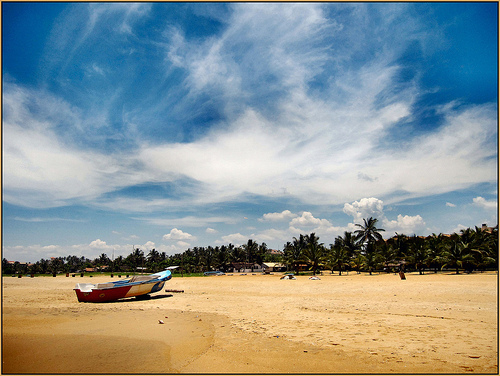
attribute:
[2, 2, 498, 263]
sky — blue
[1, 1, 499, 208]
clouds — wispy, white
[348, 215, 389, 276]
palm tree — green, tall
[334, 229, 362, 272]
palm tree — green, tall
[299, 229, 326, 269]
palm tree — green, tall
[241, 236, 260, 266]
palm tree — green, tall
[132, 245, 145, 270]
palm tree — green, tall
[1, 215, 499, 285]
trees — dense, green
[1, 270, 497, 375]
beach — brown, sandy, golden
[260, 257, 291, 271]
house — tan, brown, white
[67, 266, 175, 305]
boat — propped, tricolored, red, white, blue, resting, parked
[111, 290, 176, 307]
shadow — cast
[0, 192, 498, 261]
clouds — fluffy, white, small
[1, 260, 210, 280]
park — grassy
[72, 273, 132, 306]
back — red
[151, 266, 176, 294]
front — blue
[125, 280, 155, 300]
stripe — white